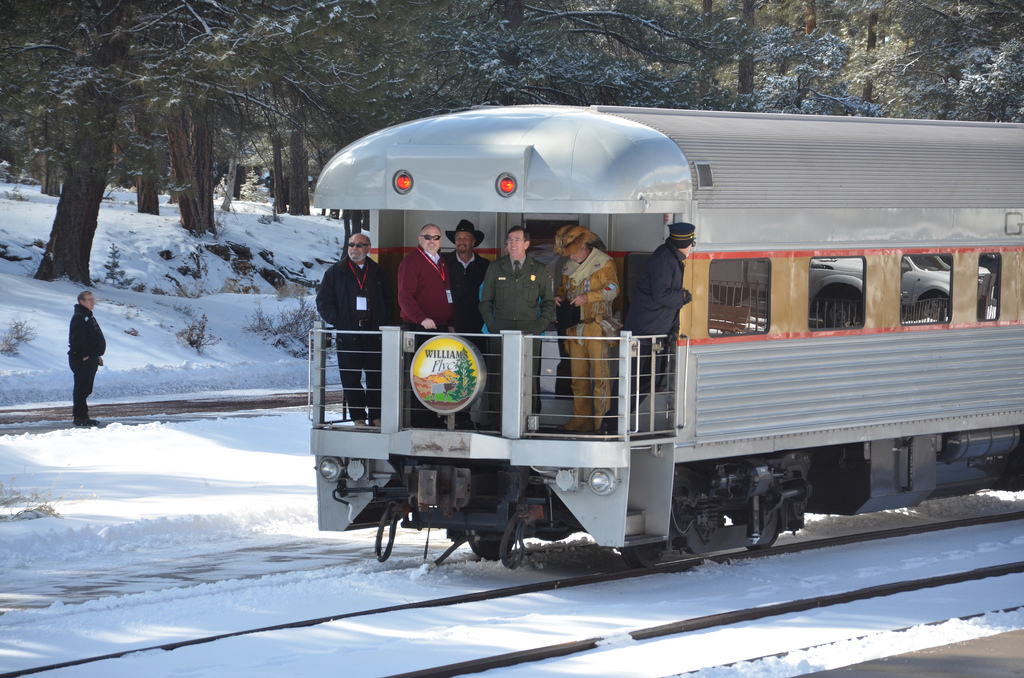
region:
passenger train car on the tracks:
[309, 100, 1018, 568]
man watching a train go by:
[68, 287, 108, 428]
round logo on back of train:
[405, 331, 489, 415]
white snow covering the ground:
[3, 161, 1022, 671]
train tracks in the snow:
[8, 507, 1023, 676]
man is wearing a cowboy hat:
[441, 217, 493, 323]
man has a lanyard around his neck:
[318, 230, 398, 424]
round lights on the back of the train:
[388, 164, 521, 199]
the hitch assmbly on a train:
[387, 459, 530, 565]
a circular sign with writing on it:
[406, 339, 483, 409]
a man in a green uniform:
[476, 231, 554, 365]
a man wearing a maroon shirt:
[393, 228, 457, 336]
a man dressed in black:
[313, 233, 383, 392]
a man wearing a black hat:
[444, 218, 484, 269]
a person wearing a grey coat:
[629, 246, 693, 348]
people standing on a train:
[282, 105, 698, 508]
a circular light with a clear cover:
[317, 458, 338, 481]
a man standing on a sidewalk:
[42, 272, 161, 446]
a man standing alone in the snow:
[67, 289, 105, 425]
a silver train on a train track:
[314, 107, 1017, 573]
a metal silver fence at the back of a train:
[308, 327, 676, 448]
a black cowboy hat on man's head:
[443, 219, 485, 248]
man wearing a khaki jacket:
[482, 254, 555, 337]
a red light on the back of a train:
[393, 172, 410, 192]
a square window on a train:
[706, 255, 773, 331]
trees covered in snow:
[0, 4, 1022, 283]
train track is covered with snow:
[0, 510, 1021, 675]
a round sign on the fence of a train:
[409, 333, 483, 413]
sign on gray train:
[394, 326, 487, 422]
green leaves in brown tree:
[64, 16, 134, 71]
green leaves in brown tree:
[201, 37, 285, 89]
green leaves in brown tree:
[506, 22, 564, 54]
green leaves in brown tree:
[658, 25, 725, 74]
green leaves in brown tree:
[889, 28, 973, 66]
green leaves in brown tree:
[55, 43, 133, 69]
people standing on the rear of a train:
[308, 105, 700, 573]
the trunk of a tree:
[29, 12, 132, 281]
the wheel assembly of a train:
[652, 461, 824, 564]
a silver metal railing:
[302, 322, 680, 433]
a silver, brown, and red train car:
[279, 92, 1022, 538]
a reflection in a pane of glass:
[801, 250, 874, 342]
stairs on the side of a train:
[602, 380, 710, 587]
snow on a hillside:
[121, 217, 271, 389]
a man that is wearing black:
[62, 284, 108, 425]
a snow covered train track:
[4, 493, 1020, 674]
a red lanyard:
[412, 236, 450, 288]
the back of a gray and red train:
[305, 101, 1021, 574]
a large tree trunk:
[27, 23, 146, 286]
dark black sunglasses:
[418, 227, 441, 243]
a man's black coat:
[64, 306, 109, 351]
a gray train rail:
[513, 322, 669, 434]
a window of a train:
[703, 250, 776, 339]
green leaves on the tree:
[288, 78, 299, 99]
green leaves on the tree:
[829, 38, 849, 138]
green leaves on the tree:
[895, 37, 972, 113]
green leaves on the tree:
[969, 54, 998, 112]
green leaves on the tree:
[286, 25, 360, 87]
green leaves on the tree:
[207, 61, 303, 134]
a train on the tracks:
[107, 89, 987, 674]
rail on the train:
[297, 288, 671, 484]